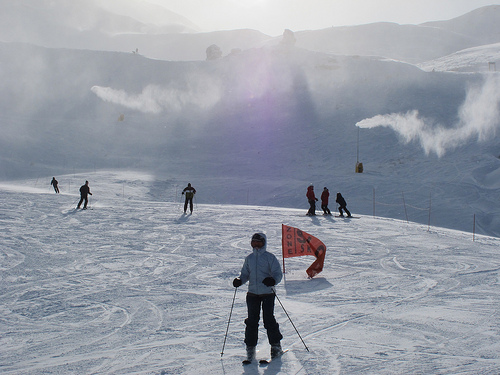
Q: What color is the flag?
A: Red.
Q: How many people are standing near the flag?
A: One.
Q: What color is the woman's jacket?
A: Blue.